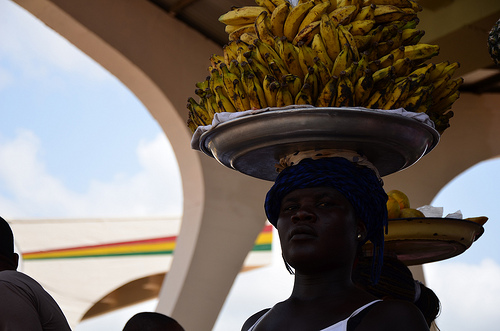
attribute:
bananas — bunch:
[185, 0, 464, 130]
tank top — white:
[238, 292, 370, 320]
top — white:
[236, 293, 385, 330]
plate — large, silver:
[189, 104, 434, 178]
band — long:
[21, 223, 275, 261]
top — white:
[234, 287, 383, 329]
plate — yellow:
[383, 212, 475, 260]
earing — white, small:
[350, 226, 373, 244]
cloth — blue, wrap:
[262, 154, 394, 289]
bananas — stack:
[185, 7, 452, 118]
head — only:
[264, 149, 389, 284]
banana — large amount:
[223, 71, 235, 86]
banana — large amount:
[218, 93, 232, 110]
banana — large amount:
[309, 33, 324, 60]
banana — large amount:
[331, 41, 348, 75]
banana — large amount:
[253, 8, 277, 43]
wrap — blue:
[260, 154, 391, 228]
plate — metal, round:
[200, 107, 440, 180]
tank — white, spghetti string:
[234, 282, 376, 328]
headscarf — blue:
[262, 159, 422, 219]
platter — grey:
[191, 71, 499, 172]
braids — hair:
[360, 254, 445, 320]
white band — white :
[406, 270, 426, 307]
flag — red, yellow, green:
[26, 228, 281, 272]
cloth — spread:
[195, 105, 247, 127]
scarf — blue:
[257, 157, 392, 191]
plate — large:
[170, 91, 440, 160]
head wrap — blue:
[258, 163, 386, 201]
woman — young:
[248, 158, 435, 327]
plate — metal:
[180, 105, 439, 168]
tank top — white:
[243, 288, 393, 329]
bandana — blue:
[240, 161, 402, 217]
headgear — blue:
[259, 150, 393, 275]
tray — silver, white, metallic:
[194, 104, 440, 181]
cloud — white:
[9, 109, 189, 215]